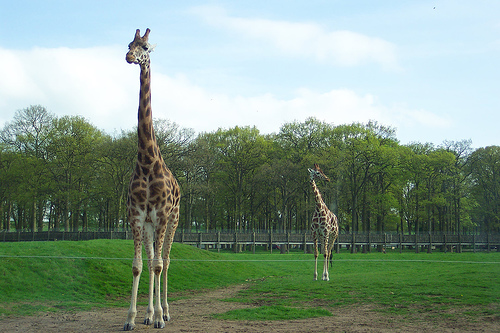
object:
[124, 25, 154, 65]
head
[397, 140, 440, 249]
trees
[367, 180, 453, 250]
set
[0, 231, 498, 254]
fence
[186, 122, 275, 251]
trees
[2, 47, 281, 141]
clouds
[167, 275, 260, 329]
dirt patch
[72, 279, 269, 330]
path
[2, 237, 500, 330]
grass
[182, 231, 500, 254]
platform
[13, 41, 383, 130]
clouds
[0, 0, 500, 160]
sky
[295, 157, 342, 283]
giraffe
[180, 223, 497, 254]
walkway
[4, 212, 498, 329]
enclosure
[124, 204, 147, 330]
giraffe's legs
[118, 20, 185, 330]
giraffe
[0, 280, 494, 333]
soil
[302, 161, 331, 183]
head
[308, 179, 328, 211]
neck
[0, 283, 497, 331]
patches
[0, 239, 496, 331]
field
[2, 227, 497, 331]
zoo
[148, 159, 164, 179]
spot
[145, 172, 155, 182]
spot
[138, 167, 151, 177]
spot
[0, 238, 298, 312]
hill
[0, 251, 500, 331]
ground